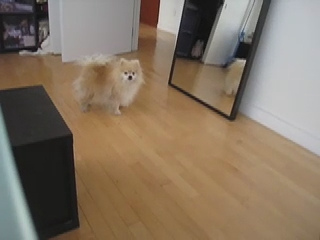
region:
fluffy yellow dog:
[73, 53, 143, 117]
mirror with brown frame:
[168, 1, 268, 119]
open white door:
[58, 1, 136, 64]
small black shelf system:
[0, 83, 80, 237]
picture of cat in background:
[2, 2, 37, 51]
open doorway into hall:
[140, 3, 182, 79]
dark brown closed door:
[140, 0, 159, 27]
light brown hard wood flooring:
[1, 19, 319, 238]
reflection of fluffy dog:
[224, 56, 246, 96]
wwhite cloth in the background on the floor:
[19, 35, 51, 55]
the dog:
[75, 35, 157, 167]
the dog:
[50, 9, 215, 216]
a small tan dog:
[74, 50, 140, 120]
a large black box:
[2, 81, 82, 232]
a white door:
[61, 0, 142, 59]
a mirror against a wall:
[153, 0, 276, 118]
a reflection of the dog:
[223, 55, 244, 102]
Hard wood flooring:
[4, 19, 317, 238]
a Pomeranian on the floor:
[72, 46, 148, 124]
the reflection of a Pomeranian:
[226, 52, 245, 97]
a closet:
[0, 0, 51, 43]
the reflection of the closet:
[176, 0, 228, 58]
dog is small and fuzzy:
[71, 52, 144, 118]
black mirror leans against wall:
[164, 0, 270, 125]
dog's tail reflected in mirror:
[221, 58, 249, 100]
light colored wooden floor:
[3, 20, 316, 237]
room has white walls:
[51, 0, 318, 157]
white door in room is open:
[59, 0, 180, 77]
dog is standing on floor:
[75, 49, 141, 116]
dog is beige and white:
[66, 49, 146, 114]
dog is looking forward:
[67, 52, 141, 116]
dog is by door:
[69, 45, 141, 122]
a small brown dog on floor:
[73, 47, 150, 121]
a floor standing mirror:
[162, 0, 264, 122]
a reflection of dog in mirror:
[219, 57, 247, 99]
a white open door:
[59, 0, 133, 70]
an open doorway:
[133, 0, 189, 82]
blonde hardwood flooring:
[3, 18, 316, 235]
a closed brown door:
[139, 0, 159, 30]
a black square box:
[3, 83, 81, 237]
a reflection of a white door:
[200, 0, 249, 64]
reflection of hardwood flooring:
[172, 57, 234, 110]